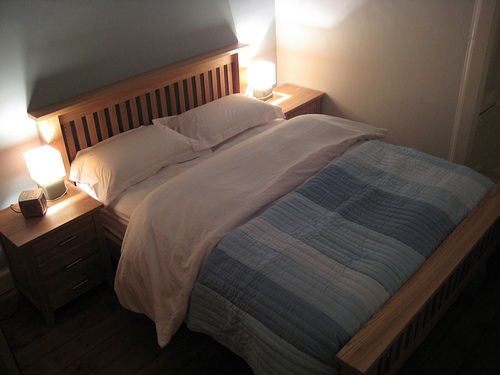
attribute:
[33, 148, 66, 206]
lamp — on, small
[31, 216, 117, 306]
nightstand — wooden, brown, small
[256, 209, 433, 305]
blanket — blue, white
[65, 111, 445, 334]
bed — wooden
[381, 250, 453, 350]
footboard — wooden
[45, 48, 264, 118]
headboard — wooden, brown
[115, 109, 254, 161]
pillows — white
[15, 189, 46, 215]
clock — square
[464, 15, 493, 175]
door — white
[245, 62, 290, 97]
light — square, shining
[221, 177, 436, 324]
comforter — blue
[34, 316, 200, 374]
floor — wood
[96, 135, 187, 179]
pillow — white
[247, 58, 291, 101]
lamp — on